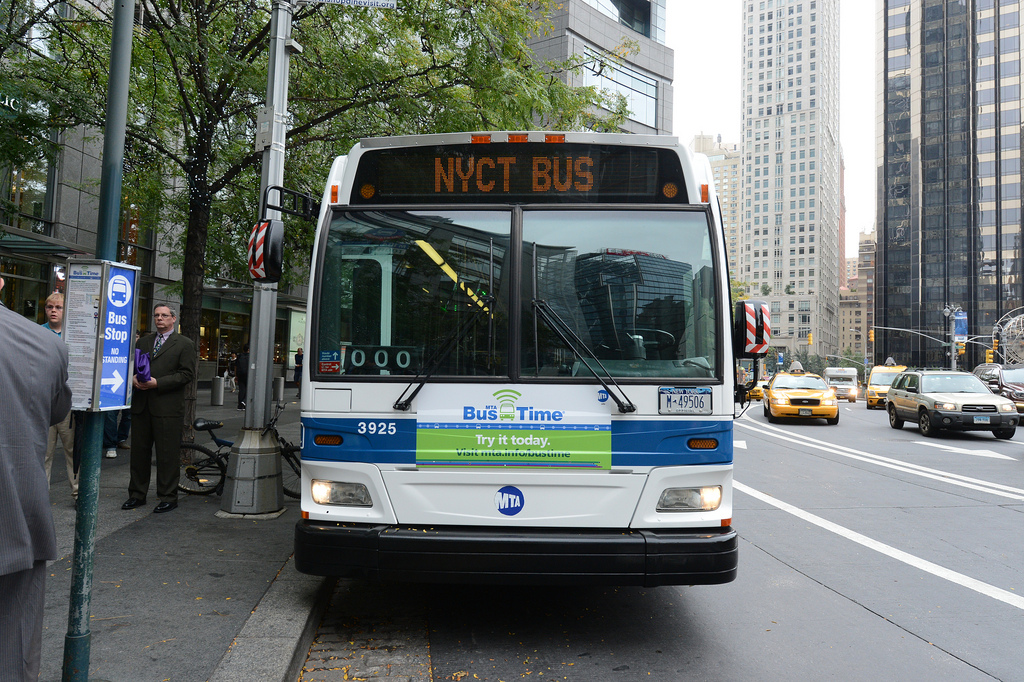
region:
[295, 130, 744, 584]
Public transportation city bus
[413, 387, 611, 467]
white, blue and green advertisment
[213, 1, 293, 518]
silver, metal city street lamp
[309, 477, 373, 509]
illuminated bus head light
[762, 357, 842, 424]
in transport city yellow cab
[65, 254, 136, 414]
bus stop sign for directions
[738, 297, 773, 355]
city bus side mirror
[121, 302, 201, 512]
man with purple umbrella standing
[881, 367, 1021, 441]
silver compact car driving down street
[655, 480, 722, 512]
light on the front of a bus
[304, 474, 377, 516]
Light on the front of a bus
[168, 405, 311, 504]
A bike leaning on a pole on the sidewalk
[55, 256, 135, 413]
A bus stop sign on a pole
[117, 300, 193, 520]
Man in a black suit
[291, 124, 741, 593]
Large white and blue bus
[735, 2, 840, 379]
Tall white building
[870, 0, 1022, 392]
Tall building covered in windows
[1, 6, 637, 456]
Green tree on the sidewalk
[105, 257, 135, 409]
blue bus stop sign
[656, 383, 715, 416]
license plate on bus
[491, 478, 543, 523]
blue MTA logo on bus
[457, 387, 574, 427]
bus time logo on front of bus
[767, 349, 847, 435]
yellow taxi driving down the road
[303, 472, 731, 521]
headlights illuminated on front of bus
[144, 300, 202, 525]
man in suit standing at bus stop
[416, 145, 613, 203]
LED destination sign on front of bus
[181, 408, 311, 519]
bike propped on metal pole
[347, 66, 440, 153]
green leaves on the tree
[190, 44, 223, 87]
green leaves on the tree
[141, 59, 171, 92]
green leaves on the tree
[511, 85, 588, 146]
green leaves on the tree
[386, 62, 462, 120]
green leaves on the tree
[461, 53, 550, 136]
green leaves on the tree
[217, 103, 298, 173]
green leaves on the tree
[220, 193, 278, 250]
green leaves on the tree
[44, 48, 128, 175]
green leaves on the tree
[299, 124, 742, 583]
blue and white bus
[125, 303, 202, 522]
man wearing a dark gray suit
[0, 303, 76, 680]
light gray suit man is wearing